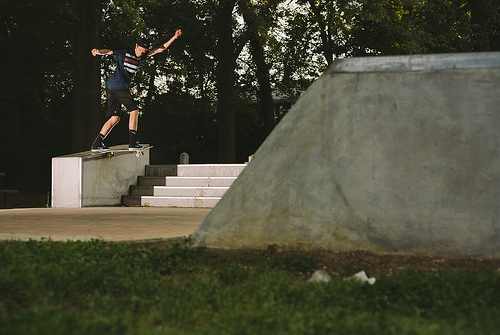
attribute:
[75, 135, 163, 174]
skate board —  doing tricks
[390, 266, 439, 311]
grass — green, a patch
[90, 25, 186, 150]
man —  on skateboard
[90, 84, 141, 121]
shorts — black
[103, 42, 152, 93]
shirt — blue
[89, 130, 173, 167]
skateboard — black, white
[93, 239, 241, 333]
grass —  small, green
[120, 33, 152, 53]
cap — baseball, black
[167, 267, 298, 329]
grass — a patch, green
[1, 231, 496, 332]
grass — green, a patch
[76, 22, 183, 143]
man —  wearing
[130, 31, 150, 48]
hat — black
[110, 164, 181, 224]
pavement — stairs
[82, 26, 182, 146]
skater — on skateboard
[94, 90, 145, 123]
shorts — black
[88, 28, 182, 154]
skater — in air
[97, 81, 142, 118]
shorts — short, black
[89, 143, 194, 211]
shadows — dark